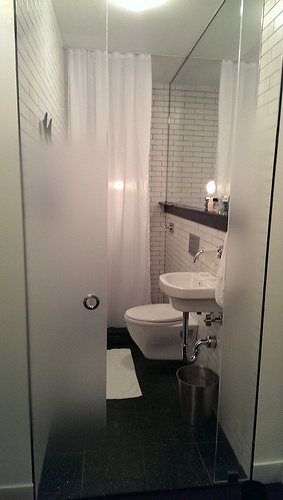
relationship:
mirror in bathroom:
[15, 0, 282, 499] [58, 48, 181, 264]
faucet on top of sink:
[193, 246, 223, 262] [159, 270, 222, 311]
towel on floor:
[106, 345, 139, 398] [0, 327, 283, 496]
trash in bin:
[184, 373, 207, 385] [173, 362, 216, 426]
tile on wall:
[151, 82, 164, 90] [144, 80, 219, 304]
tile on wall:
[148, 180, 164, 190] [144, 80, 219, 304]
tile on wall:
[146, 220, 162, 229] [144, 80, 219, 304]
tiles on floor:
[50, 342, 237, 485] [29, 319, 275, 497]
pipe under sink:
[179, 310, 219, 364] [157, 268, 217, 308]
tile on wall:
[151, 82, 164, 90] [155, 82, 174, 283]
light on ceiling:
[104, 2, 164, 17] [50, 0, 227, 55]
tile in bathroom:
[151, 82, 164, 90] [15, 3, 221, 429]